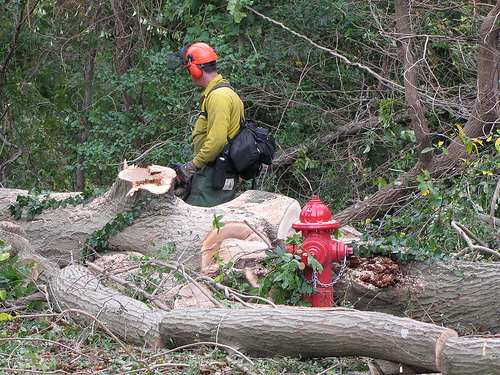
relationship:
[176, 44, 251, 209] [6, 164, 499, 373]
man cutting tree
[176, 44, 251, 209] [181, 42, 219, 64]
man wearing helmet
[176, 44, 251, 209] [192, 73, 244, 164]
man wearing jacket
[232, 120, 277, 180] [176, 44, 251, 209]
backpack on man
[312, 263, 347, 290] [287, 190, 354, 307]
chain on fire hydrant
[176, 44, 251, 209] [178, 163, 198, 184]
man wearing glove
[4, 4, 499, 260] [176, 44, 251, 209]
brush behind man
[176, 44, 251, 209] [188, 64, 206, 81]
man wearing ear muffs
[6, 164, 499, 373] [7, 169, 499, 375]
tree on ground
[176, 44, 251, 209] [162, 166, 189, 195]
man holding saw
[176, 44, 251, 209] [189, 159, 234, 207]
man wearing pant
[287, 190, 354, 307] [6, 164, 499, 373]
fire hydrant near tree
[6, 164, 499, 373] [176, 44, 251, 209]
tree next to man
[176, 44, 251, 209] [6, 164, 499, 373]
man next to tree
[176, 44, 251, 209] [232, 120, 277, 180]
man wearing backpack